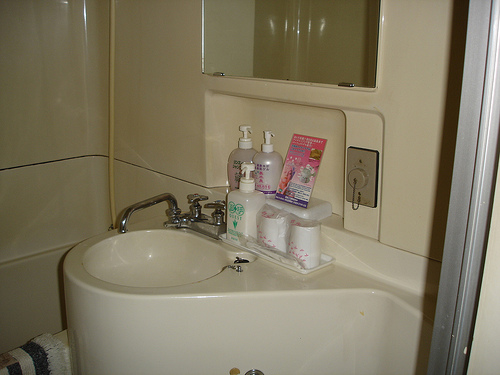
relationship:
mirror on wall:
[197, 2, 382, 92] [106, 9, 461, 289]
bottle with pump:
[252, 130, 285, 196] [258, 127, 273, 152]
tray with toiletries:
[217, 225, 334, 274] [223, 161, 323, 260]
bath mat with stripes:
[6, 330, 63, 371] [10, 339, 50, 373]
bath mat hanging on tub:
[6, 332, 73, 375] [6, 237, 73, 372]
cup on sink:
[287, 217, 322, 271] [57, 217, 288, 345]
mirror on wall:
[197, 2, 382, 92] [100, 3, 460, 256]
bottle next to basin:
[225, 160, 265, 238] [80, 227, 255, 289]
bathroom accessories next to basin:
[224, 126, 259, 192] [80, 227, 255, 289]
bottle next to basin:
[252, 130, 285, 196] [80, 227, 255, 289]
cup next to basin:
[258, 206, 293, 253] [80, 227, 255, 289]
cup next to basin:
[287, 216, 325, 268] [80, 227, 255, 289]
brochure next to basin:
[272, 130, 330, 210] [80, 227, 255, 289]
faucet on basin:
[111, 189, 184, 234] [80, 227, 255, 289]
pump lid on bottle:
[237, 123, 255, 150] [227, 122, 261, 191]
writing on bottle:
[226, 199, 246, 231] [225, 160, 265, 238]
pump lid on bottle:
[257, 126, 280, 153] [254, 127, 284, 190]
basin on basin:
[83, 229, 231, 287] [80, 227, 255, 289]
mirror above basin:
[197, 2, 382, 92] [80, 227, 255, 289]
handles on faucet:
[183, 190, 228, 224] [113, 189, 227, 236]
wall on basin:
[61, 270, 435, 373] [80, 227, 255, 289]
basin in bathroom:
[80, 227, 255, 289] [3, 2, 499, 373]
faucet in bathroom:
[111, 186, 228, 235] [3, 2, 499, 373]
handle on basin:
[183, 187, 207, 218] [80, 227, 255, 289]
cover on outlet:
[348, 167, 365, 209] [341, 143, 381, 211]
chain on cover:
[346, 186, 364, 213] [345, 165, 370, 192]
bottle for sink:
[224, 161, 266, 240] [60, 214, 424, 373]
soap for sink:
[262, 190, 333, 219] [60, 214, 424, 373]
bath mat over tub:
[6, 332, 73, 375] [1, 240, 90, 346]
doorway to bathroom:
[427, 0, 498, 371] [3, 2, 499, 373]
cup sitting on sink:
[255, 206, 293, 256] [62, 214, 361, 370]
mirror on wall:
[197, 2, 382, 92] [112, 0, 469, 306]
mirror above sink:
[197, 2, 382, 92] [62, 214, 361, 370]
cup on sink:
[287, 217, 322, 271] [60, 214, 424, 373]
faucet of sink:
[111, 189, 184, 234] [62, 214, 361, 370]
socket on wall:
[343, 145, 378, 206] [112, 0, 469, 306]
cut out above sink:
[204, 93, 347, 226] [62, 214, 361, 370]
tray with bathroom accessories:
[217, 225, 334, 274] [227, 161, 321, 267]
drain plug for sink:
[235, 254, 250, 270] [60, 222, 384, 368]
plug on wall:
[340, 145, 378, 208] [112, 0, 469, 306]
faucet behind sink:
[111, 189, 184, 234] [62, 214, 361, 370]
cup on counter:
[255, 206, 293, 256] [200, 217, 333, 270]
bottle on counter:
[224, 161, 266, 240] [215, 220, 345, 271]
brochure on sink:
[272, 130, 330, 210] [62, 214, 361, 370]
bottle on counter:
[252, 130, 285, 196] [154, 210, 371, 292]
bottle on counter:
[230, 111, 280, 211] [174, 81, 404, 314]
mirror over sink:
[198, 21, 471, 127] [65, 211, 357, 351]